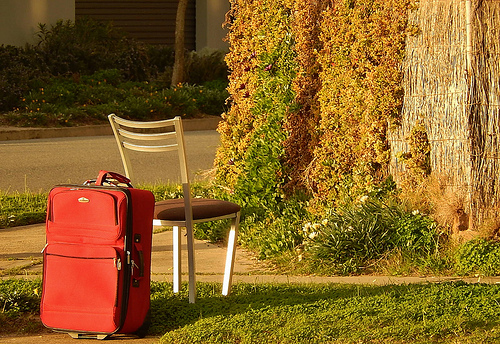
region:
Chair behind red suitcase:
[106, 111, 242, 301]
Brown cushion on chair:
[150, 196, 239, 219]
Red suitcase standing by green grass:
[37, 172, 154, 340]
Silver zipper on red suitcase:
[39, 241, 48, 253]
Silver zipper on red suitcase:
[113, 258, 123, 271]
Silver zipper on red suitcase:
[124, 248, 131, 263]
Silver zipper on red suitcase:
[131, 259, 140, 269]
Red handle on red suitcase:
[130, 231, 146, 288]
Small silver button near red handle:
[133, 235, 140, 242]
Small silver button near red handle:
[132, 277, 139, 284]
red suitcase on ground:
[39, 170, 154, 339]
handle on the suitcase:
[85, 174, 118, 188]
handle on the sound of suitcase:
[135, 240, 150, 284]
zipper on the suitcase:
[122, 251, 133, 266]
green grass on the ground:
[241, 285, 489, 341]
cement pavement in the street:
[2, 136, 83, 184]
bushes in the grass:
[26, 39, 113, 71]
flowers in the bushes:
[34, 86, 51, 104]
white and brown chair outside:
[109, 113, 248, 300]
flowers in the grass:
[356, 193, 371, 209]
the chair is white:
[104, 102, 244, 302]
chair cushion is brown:
[147, 192, 239, 229]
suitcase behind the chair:
[32, 164, 159, 339]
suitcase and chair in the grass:
[18, 79, 268, 341]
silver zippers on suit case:
[35, 239, 147, 282]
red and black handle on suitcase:
[129, 229, 149, 291]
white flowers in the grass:
[283, 182, 421, 262]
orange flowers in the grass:
[5, 74, 222, 117]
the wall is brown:
[73, 2, 197, 55]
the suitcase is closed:
[23, 154, 155, 340]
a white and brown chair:
[107, 111, 244, 294]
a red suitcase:
[48, 163, 167, 341]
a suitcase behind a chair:
[27, 104, 244, 331]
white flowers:
[273, 188, 369, 257]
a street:
[0, 135, 233, 176]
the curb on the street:
[7, 123, 209, 133]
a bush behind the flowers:
[10, 20, 141, 78]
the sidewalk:
[177, 253, 492, 305]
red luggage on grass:
[28, 170, 155, 335]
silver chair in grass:
[113, 115, 254, 292]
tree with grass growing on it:
[231, 2, 497, 236]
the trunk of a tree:
[412, 5, 494, 230]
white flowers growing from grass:
[279, 192, 363, 264]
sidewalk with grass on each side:
[270, 266, 472, 309]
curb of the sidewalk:
[6, 131, 81, 143]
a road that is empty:
[7, 137, 84, 189]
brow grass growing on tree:
[316, 1, 406, 203]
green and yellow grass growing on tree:
[242, 55, 291, 210]